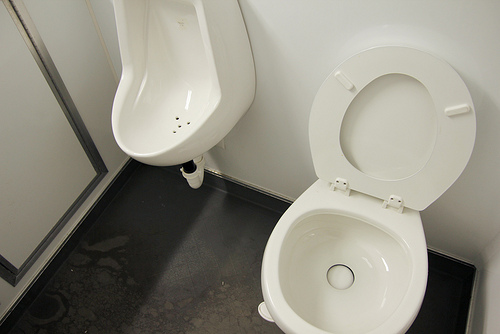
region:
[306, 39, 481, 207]
white toilet seat lifted up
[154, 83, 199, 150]
four holes in the bottom of a urinal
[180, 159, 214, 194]
pipe going from the wall to the urinal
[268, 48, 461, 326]
white toilet next to a urinal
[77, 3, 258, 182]
white urinal next to a toilet with the seat up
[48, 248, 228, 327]
a lot of spots on the bathroom floor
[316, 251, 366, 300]
water in the basin of the toilet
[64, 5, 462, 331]
urinal and toilet next to each other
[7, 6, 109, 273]
small door in the wall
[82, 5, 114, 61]
caulk in the corner of the wall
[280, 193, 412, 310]
white toilet bowl in bathroom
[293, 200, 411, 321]
white toilet bowl with lid up in bathroom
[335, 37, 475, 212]
white toilet seat in bathroom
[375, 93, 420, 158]
white toilet lid in bathroom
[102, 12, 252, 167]
white urinal in bathroom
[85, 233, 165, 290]
gray floor in bath room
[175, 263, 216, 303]
gray floor in bath room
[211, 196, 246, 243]
gray floor in bath room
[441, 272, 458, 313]
gray floor in bath room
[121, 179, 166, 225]
gray floor in bath room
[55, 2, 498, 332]
white toilet and white urinal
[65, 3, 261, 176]
white urinal hanging on wall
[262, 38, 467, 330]
toilet with the lid up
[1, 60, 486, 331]
bathroom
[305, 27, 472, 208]
the open lid of a toilet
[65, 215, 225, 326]
bathroom floor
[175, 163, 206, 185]
pvc plumbing fitting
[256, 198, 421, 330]
bowl portion of a commode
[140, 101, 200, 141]
drain portion of a urinal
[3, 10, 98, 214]
portion of bathroom wall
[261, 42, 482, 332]
white clean toilet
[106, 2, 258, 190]
white clean bidet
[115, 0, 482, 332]
white bidet and white toilet in a bathroom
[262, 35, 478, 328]
white toilet with open top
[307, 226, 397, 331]
clean water in white toilet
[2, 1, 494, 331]
white walls in the bottom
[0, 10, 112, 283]
gray metal door frame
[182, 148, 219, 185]
white pipeline under bidet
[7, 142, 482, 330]
black floor in bathroom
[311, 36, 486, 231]
open top of a toilet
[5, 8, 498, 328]
An image in restroom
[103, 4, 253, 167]
Male urinal is white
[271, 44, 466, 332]
A white toilet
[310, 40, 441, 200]
The toilet seat is up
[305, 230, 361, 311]
The toilet drain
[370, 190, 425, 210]
toilet seat hinge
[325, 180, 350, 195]
toilet seat hinge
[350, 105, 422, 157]
Toilet lid under seat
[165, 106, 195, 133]
urinal has a drain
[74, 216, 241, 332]
floor is black